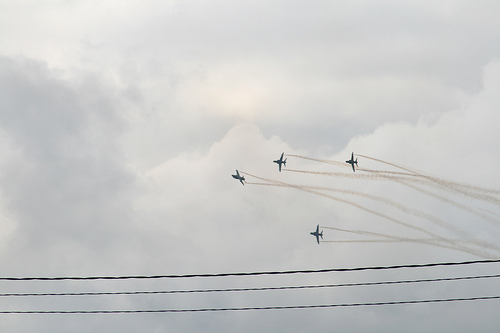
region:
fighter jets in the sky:
[183, 102, 366, 252]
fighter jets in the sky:
[301, 139, 370, 258]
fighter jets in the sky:
[211, 133, 301, 196]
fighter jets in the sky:
[269, 135, 339, 252]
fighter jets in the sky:
[219, 105, 359, 192]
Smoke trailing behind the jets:
[236, 153, 498, 260]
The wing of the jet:
[351, 152, 356, 170]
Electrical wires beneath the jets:
[0, 259, 498, 315]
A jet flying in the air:
[231, 169, 246, 183]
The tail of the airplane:
[283, 155, 288, 165]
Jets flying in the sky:
[230, 153, 360, 243]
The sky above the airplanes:
[0, 1, 497, 331]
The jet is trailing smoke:
[348, 153, 361, 170]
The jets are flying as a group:
[231, 153, 359, 244]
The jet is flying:
[273, 153, 288, 172]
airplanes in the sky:
[255, 153, 407, 254]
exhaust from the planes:
[425, 178, 482, 256]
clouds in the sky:
[2, 127, 209, 251]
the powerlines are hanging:
[118, 279, 422, 309]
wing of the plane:
[310, 238, 325, 243]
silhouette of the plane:
[303, 225, 330, 252]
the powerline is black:
[225, 268, 250, 276]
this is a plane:
[303, 200, 328, 252]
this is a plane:
[335, 139, 370, 184]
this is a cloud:
[104, 100, 164, 177]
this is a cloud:
[258, 92, 323, 154]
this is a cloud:
[25, 101, 85, 195]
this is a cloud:
[444, 77, 483, 169]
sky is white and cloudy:
[0, 0, 499, 330]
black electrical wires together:
[0, 258, 499, 331]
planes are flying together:
[232, 152, 359, 244]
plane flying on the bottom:
[309, 225, 324, 245]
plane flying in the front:
[232, 168, 247, 185]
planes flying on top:
[273, 150, 359, 173]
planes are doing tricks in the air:
[237, 148, 358, 244]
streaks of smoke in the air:
[241, 152, 499, 261]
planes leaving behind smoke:
[234, 148, 499, 258]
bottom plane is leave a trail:
[311, 223, 498, 260]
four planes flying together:
[227, 140, 372, 255]